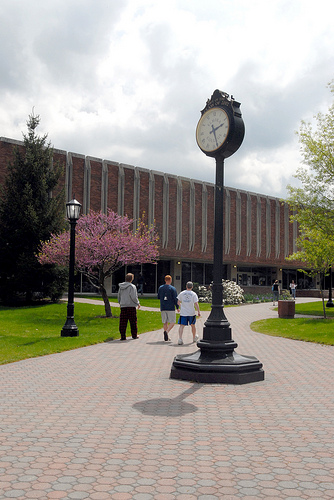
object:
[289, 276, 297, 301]
person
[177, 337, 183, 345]
sneaker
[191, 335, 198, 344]
sneaker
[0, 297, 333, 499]
sidewalk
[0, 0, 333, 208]
sky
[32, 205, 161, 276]
blossoms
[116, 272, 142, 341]
guy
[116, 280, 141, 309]
grey jacket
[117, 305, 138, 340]
pants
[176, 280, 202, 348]
boy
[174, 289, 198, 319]
shirt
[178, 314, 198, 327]
shorts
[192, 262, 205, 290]
windows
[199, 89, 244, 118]
ornamentation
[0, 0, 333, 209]
clouds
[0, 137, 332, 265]
wall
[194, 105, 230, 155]
clock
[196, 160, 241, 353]
pole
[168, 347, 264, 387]
foundation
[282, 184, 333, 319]
green tree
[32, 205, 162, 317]
tree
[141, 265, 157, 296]
window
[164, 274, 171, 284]
hair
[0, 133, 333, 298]
building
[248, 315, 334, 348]
grass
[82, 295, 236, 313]
grass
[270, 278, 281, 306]
women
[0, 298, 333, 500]
pavers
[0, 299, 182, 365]
grass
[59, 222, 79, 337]
lamp post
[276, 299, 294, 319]
receptacle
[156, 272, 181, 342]
guy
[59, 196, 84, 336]
street light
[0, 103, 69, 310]
tree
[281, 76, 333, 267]
tree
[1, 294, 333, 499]
campus